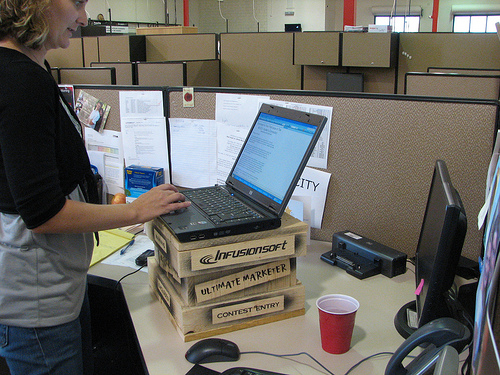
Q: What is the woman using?
A: A laptop.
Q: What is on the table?
A: A red cup.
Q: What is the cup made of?
A: Plastic.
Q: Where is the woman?
A: In a cubicle.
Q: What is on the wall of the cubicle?
A: Papers.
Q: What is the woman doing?
A: Typing on a laptop.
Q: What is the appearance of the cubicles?
A: Brown with dark trim.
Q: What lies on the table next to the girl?
A: A black computer mouse with cord.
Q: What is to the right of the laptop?
A: Black flat screen monitor.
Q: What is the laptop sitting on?
A: Brown wooden box.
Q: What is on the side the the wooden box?
A: Writing.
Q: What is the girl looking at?
A: A laptop computer screen.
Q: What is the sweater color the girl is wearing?
A: Black.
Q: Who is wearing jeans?
A: The woman using laptop.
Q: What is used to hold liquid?
A: Cup.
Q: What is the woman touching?
A: Laptop.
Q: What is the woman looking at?
A: Laptop.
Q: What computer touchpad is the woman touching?
A: Laptop.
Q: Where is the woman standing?
A: In office.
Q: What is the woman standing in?
A: Cubicle.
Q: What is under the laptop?
A: Stacked boxes.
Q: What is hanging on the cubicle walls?
A: Papers.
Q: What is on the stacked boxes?
A: Laptop.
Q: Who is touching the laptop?
A: The woman.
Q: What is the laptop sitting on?
A: Boxes.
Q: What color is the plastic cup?
A: Red.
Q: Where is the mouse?
A: On the desk.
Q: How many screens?
A: Two.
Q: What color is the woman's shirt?
A: Gray.